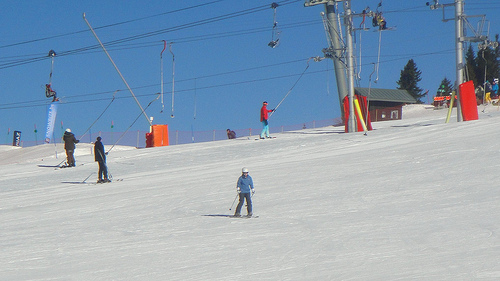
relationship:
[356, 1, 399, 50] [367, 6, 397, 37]
skier on lift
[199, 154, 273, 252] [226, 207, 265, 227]
person on ski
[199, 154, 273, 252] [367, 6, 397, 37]
person on lift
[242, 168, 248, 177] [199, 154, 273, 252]
head of person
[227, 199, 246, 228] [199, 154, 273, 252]
leg of person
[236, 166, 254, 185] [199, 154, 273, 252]
head of person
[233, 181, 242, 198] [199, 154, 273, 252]
arm of person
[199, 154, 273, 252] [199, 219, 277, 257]
person on snow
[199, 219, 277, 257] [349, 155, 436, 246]
snow in mountain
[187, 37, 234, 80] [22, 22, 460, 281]
cloud in photo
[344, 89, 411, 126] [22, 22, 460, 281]
house in photo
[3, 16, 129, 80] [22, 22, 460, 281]
cable in photo